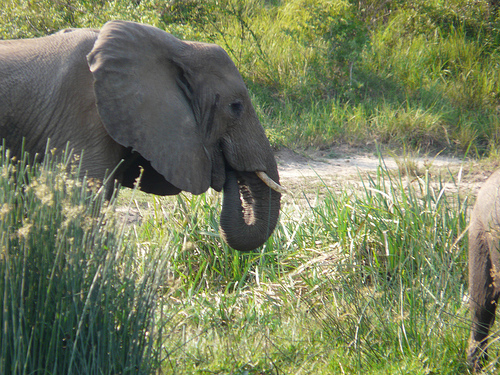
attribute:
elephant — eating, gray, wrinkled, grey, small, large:
[26, 41, 321, 246]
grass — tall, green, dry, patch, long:
[53, 224, 423, 374]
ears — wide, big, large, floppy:
[90, 33, 195, 200]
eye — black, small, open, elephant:
[213, 95, 258, 122]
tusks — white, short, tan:
[254, 168, 289, 204]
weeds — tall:
[339, 168, 466, 353]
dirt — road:
[294, 170, 372, 219]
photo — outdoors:
[23, 29, 495, 324]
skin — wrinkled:
[13, 94, 109, 163]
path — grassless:
[263, 149, 500, 194]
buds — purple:
[49, 211, 107, 261]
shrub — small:
[44, 166, 171, 367]